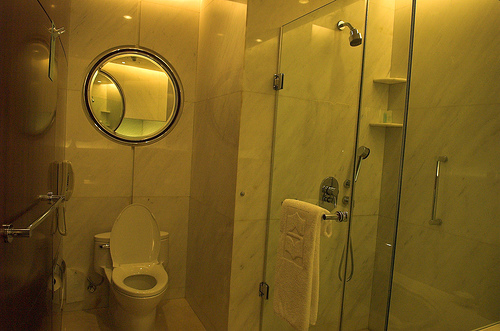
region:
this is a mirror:
[68, 43, 186, 175]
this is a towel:
[263, 187, 339, 329]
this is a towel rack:
[12, 179, 92, 260]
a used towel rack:
[268, 178, 358, 253]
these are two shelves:
[371, 66, 426, 148]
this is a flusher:
[91, 233, 113, 255]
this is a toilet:
[77, 203, 187, 329]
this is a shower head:
[333, 21, 376, 53]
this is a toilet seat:
[106, 250, 175, 297]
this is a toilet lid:
[97, 206, 177, 269]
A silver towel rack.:
[8, 189, 66, 236]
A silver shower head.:
[340, 14, 365, 47]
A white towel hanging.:
[271, 195, 320, 326]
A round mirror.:
[84, 47, 189, 144]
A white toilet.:
[86, 221, 174, 327]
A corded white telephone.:
[55, 156, 78, 238]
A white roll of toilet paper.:
[50, 276, 65, 306]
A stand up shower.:
[265, 9, 498, 329]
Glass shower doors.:
[258, 14, 498, 329]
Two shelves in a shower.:
[369, 73, 410, 132]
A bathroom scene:
[3, 1, 497, 329]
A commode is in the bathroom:
[91, 201, 172, 329]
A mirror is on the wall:
[79, 41, 184, 146]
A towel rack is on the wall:
[3, 189, 69, 242]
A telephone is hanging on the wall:
[51, 156, 76, 236]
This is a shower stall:
[255, 0, 498, 328]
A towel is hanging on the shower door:
[269, 194, 344, 329]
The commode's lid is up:
[109, 202, 163, 270]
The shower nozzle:
[336, 17, 363, 48]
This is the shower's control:
[318, 174, 342, 208]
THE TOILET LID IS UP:
[101, 194, 168, 278]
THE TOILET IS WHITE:
[91, 194, 173, 329]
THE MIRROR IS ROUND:
[77, 40, 189, 149]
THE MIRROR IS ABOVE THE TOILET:
[80, 40, 183, 160]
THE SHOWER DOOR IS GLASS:
[268, 0, 497, 330]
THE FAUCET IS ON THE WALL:
[310, 141, 387, 301]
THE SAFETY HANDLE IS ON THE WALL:
[1, 181, 70, 254]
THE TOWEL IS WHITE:
[264, 190, 328, 330]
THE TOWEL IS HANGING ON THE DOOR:
[259, 187, 343, 329]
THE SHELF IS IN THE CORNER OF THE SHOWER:
[362, 61, 409, 151]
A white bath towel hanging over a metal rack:
[270, 196, 346, 330]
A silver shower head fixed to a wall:
[335, 19, 364, 49]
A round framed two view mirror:
[78, 43, 185, 147]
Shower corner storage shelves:
[366, 75, 407, 131]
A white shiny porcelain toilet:
[89, 201, 170, 330]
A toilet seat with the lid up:
[106, 202, 169, 299]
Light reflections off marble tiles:
[121, 12, 264, 44]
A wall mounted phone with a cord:
[53, 158, 76, 238]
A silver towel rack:
[0, 190, 67, 245]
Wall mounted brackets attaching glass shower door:
[255, 70, 286, 302]